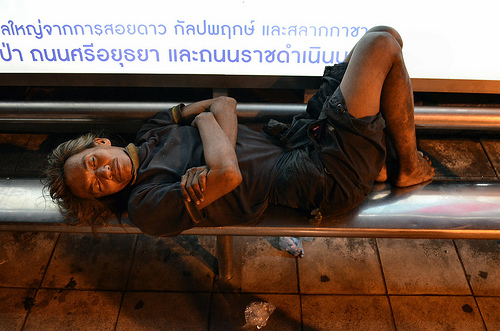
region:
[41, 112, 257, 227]
the man is sleeping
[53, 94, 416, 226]
man is sleeping on the bench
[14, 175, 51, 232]
the bench is silver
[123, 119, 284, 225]
man's shirt is black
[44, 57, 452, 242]
the man is dirty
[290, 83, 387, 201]
man's short is black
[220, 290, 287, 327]
plastic bag on the ground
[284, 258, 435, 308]
the floor is dirty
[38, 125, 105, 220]
man's hair is brown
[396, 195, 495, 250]
the bench is stainless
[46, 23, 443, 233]
man sleeping on a bench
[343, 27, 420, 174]
man's dirty legs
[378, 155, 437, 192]
dirty bare feet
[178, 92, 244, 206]
arms are crossed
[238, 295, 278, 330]
clear piece of plastic on the ground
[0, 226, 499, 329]
cement squares on ground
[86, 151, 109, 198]
eyes are both closed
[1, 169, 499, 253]
shiny metal bench seat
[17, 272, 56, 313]
dark stain on cement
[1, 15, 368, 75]
blue lettering on a white background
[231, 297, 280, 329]
large clear object on ground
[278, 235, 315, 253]
white crumbled paper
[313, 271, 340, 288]
small black spot on ground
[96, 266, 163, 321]
black lines in brown tiles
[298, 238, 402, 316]
large brown square tile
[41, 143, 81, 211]
dark blond hair on man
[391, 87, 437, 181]
caked dirt on man's foot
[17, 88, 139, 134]
large square silver railing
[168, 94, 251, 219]
man's arms folded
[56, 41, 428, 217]
man laying on ground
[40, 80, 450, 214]
a homeless man sleeping on a bench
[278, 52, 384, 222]
a person wearing shorts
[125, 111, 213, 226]
a person wearing a black short sleeved shirt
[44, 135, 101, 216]
a person with brown hair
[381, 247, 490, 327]
brown tile on the floor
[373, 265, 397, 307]
black grout between tiles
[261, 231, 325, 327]
garbage on the floor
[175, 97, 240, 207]
a person with crossed arms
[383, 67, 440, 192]
a person with dirty leg and foot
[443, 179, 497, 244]
a shinny metal bench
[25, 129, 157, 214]
The man is sleeping.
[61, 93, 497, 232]
The man a lying on a bench.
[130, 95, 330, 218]
The man is wearing a t shirt.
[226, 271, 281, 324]
There is garbage under the bench.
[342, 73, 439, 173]
The man is dirty.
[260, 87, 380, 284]
the man is wearing shorts.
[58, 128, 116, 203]
The man has his eyes closed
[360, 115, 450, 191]
The man is not wearing shoes.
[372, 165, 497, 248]
The bench is metal.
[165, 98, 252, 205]
The man has his arms crossed.